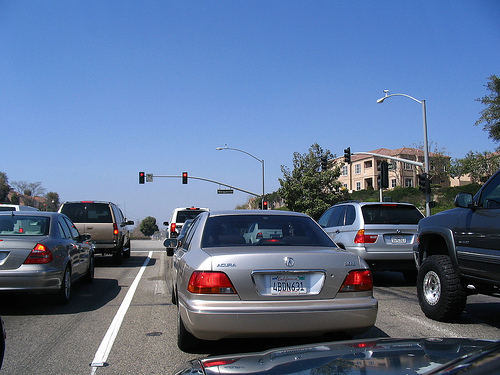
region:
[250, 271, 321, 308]
small white license plate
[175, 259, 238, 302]
red light on back of car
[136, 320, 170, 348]
small stain on the ground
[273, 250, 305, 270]
logo on back of car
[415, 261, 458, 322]
large wheel on truck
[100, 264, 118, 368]
solid white line in street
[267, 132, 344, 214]
tall green tree on sidewalk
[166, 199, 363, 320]
silver car on road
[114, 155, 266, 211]
overhead black traffic lights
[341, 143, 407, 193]
pink house with brown roof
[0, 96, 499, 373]
a traffic jam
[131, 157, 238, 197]
the lights are red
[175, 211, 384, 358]
the acura is gold in color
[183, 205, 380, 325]
it has California tags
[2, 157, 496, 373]
it appears to be four lanes of traffic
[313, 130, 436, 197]
a spanish style building is on the hill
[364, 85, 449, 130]
an over head light with a camera attached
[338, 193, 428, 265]
this car is silver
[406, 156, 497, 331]
this truck is black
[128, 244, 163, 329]
a white stripe seperates the lanes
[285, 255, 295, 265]
The Acura logo.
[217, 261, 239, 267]
The Acura wordmark.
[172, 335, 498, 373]
A car waiting in traffic.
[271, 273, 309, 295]
A license plate.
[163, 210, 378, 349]
A car waiting in traffic.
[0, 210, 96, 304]
A car waiting in traffic.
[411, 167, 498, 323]
A truck waiting in traffic.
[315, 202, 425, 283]
A minivan waiting in traffic.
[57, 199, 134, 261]
An SUV waiting in traffic.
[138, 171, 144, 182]
A traffic light.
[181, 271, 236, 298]
the tail light of a car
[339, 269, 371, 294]
the tail light of a car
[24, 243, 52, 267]
the tail light of a car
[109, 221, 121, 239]
the tail light of a car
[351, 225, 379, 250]
the tail light of a car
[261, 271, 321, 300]
the license plate of a car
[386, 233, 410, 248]
the license plate of a car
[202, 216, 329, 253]
the rear window of a car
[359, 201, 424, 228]
the rear window of a car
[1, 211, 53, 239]
the rear window of a car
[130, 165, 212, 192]
two traffic lights showing red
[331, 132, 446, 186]
a tall building with a shingled roof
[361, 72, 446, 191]
a metal light pole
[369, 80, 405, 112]
a traffic camera on a pole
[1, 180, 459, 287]
several cars stopped at a traffic light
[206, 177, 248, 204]
a street sign hanging from a pole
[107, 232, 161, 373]
white line painted on a road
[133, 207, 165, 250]
a green tree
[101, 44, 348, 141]
a clear blue sky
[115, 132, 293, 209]
three traffic lights on a pole